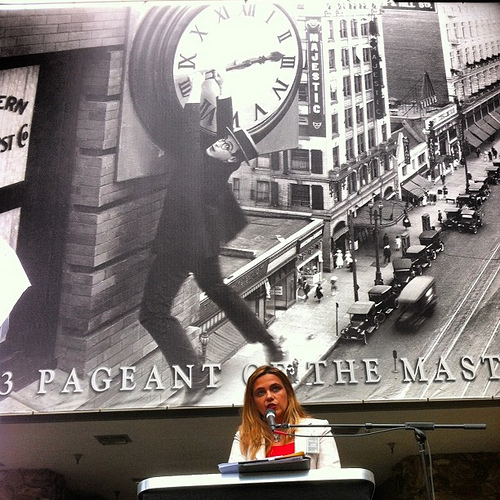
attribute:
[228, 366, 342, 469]
woman — talking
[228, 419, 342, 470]
jacket — white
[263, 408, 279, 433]
microphone — in forefront, black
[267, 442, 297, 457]
shirt — red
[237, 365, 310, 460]
hair — blonde, straight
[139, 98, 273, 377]
suit — dark, black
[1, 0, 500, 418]
photo — black, white, city setting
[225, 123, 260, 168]
hat — black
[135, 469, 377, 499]
podium — silver, in forefront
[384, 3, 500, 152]
building — large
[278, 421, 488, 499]
stand — black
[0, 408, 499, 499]
ceiling — white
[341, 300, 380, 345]
vehicle — old, parked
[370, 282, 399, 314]
vehicle — old, parked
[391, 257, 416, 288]
vehicle — old, parked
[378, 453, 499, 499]
pillar — stone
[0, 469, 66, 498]
pillar — stone